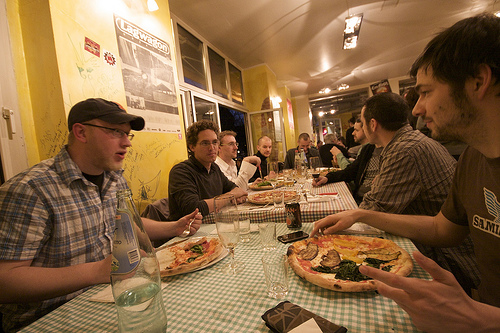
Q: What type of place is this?
A: It is a restaurant.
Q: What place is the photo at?
A: It is at the restaurant.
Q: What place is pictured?
A: It is a restaurant.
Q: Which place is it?
A: It is a restaurant.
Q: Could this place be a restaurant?
A: Yes, it is a restaurant.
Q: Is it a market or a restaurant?
A: It is a restaurant.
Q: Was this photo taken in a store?
A: No, the picture was taken in a restaurant.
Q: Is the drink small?
A: Yes, the drink is small.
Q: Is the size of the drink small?
A: Yes, the drink is small.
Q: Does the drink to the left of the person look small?
A: Yes, the drink is small.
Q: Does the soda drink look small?
A: Yes, the drink is small.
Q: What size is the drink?
A: The drink is small.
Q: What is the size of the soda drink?
A: The drink is small.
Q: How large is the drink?
A: The drink is small.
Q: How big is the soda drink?
A: The drink is small.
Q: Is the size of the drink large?
A: No, the drink is small.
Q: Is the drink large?
A: No, the drink is small.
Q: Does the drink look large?
A: No, the drink is small.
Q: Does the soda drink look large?
A: No, the drink is small.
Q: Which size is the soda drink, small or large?
A: The drink is small.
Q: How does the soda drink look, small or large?
A: The drink is small.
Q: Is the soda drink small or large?
A: The drink is small.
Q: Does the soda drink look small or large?
A: The drink is small.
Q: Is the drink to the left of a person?
A: Yes, the drink is to the left of a person.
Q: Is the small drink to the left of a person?
A: Yes, the drink is to the left of a person.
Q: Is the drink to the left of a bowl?
A: No, the drink is to the left of a person.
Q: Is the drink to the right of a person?
A: No, the drink is to the left of a person.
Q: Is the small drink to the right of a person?
A: No, the drink is to the left of a person.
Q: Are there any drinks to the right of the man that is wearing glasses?
A: Yes, there is a drink to the right of the man.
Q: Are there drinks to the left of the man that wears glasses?
A: No, the drink is to the right of the man.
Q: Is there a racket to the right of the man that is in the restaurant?
A: No, there is a drink to the right of the man.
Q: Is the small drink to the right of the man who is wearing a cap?
A: Yes, the drink is to the right of the man.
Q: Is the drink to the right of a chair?
A: No, the drink is to the right of the man.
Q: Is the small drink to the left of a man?
A: No, the drink is to the right of a man.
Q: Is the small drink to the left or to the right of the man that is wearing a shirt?
A: The drink is to the right of the man.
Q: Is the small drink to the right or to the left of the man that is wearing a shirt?
A: The drink is to the right of the man.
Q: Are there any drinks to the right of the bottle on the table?
A: Yes, there is a drink to the right of the bottle.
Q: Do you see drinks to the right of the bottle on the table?
A: Yes, there is a drink to the right of the bottle.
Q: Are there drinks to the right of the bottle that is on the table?
A: Yes, there is a drink to the right of the bottle.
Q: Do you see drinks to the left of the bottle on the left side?
A: No, the drink is to the right of the bottle.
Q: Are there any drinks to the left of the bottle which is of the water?
A: No, the drink is to the right of the bottle.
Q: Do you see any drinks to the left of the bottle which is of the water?
A: No, the drink is to the right of the bottle.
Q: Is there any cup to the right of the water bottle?
A: No, there is a drink to the right of the bottle.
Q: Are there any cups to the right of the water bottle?
A: No, there is a drink to the right of the bottle.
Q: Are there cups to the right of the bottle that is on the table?
A: No, there is a drink to the right of the bottle.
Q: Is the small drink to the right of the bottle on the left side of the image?
A: Yes, the drink is to the right of the bottle.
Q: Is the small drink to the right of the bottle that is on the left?
A: Yes, the drink is to the right of the bottle.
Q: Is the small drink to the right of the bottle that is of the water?
A: Yes, the drink is to the right of the bottle.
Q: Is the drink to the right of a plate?
A: No, the drink is to the right of the bottle.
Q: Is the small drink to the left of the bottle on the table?
A: No, the drink is to the right of the bottle.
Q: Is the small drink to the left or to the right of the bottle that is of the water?
A: The drink is to the right of the bottle.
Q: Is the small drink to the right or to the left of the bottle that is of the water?
A: The drink is to the right of the bottle.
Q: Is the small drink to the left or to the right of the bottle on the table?
A: The drink is to the right of the bottle.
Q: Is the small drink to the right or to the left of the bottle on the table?
A: The drink is to the right of the bottle.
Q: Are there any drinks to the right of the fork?
A: Yes, there is a drink to the right of the fork.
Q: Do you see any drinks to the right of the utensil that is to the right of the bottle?
A: Yes, there is a drink to the right of the fork.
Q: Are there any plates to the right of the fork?
A: No, there is a drink to the right of the fork.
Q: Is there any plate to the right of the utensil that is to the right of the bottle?
A: No, there is a drink to the right of the fork.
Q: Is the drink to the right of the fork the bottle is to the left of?
A: Yes, the drink is to the right of the fork.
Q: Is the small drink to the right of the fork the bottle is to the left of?
A: Yes, the drink is to the right of the fork.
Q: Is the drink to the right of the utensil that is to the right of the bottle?
A: Yes, the drink is to the right of the fork.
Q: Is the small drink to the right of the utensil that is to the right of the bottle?
A: Yes, the drink is to the right of the fork.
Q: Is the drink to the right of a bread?
A: No, the drink is to the right of the fork.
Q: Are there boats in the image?
A: No, there are no boats.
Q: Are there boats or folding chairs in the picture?
A: No, there are no boats or folding chairs.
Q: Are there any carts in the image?
A: No, there are no carts.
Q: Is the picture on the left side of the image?
A: Yes, the picture is on the left of the image.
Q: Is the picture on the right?
A: No, the picture is on the left of the image.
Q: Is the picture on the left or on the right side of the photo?
A: The picture is on the left of the image.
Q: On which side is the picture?
A: The picture is on the left of the image.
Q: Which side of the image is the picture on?
A: The picture is on the left of the image.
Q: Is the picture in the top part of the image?
A: Yes, the picture is in the top of the image.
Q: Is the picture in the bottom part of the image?
A: No, the picture is in the top of the image.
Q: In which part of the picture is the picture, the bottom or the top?
A: The picture is in the top of the image.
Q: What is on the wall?
A: The picture is on the wall.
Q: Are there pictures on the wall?
A: Yes, there is a picture on the wall.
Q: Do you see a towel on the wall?
A: No, there is a picture on the wall.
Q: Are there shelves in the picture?
A: No, there are no shelves.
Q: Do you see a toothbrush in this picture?
A: No, there are no toothbrushes.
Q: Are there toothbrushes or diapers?
A: No, there are no toothbrushes or diapers.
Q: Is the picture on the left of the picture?
A: Yes, the picture is on the left of the image.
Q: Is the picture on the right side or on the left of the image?
A: The picture is on the left of the image.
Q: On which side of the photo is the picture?
A: The picture is on the left of the image.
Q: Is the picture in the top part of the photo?
A: Yes, the picture is in the top of the image.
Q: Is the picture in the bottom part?
A: No, the picture is in the top of the image.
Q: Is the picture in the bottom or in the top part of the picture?
A: The picture is in the top of the image.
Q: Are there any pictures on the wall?
A: Yes, there is a picture on the wall.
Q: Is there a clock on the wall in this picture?
A: No, there is a picture on the wall.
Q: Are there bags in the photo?
A: No, there are no bags.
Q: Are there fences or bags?
A: No, there are no bags or fences.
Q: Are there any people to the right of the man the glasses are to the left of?
A: Yes, there is a person to the right of the man.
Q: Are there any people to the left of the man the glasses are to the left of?
A: No, the person is to the right of the man.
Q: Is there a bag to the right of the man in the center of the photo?
A: No, there is a person to the right of the man.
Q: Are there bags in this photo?
A: No, there are no bags.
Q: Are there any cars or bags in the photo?
A: No, there are no bags or cars.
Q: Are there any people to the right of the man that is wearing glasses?
A: Yes, there is a person to the right of the man.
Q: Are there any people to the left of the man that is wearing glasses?
A: No, the person is to the right of the man.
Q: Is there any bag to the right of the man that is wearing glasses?
A: No, there is a person to the right of the man.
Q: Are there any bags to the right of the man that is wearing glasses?
A: No, there is a person to the right of the man.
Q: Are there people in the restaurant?
A: Yes, there is a person in the restaurant.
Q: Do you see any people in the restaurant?
A: Yes, there is a person in the restaurant.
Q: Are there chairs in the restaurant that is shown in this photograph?
A: No, there is a person in the restaurant.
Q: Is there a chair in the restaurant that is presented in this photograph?
A: No, there is a person in the restaurant.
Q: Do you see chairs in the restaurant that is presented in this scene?
A: No, there is a person in the restaurant.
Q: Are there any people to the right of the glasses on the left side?
A: Yes, there is a person to the right of the glasses.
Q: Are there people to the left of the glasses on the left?
A: No, the person is to the right of the glasses.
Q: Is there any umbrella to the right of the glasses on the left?
A: No, there is a person to the right of the glasses.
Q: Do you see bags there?
A: No, there are no bags.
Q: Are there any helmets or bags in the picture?
A: No, there are no bags or helmets.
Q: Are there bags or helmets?
A: No, there are no bags or helmets.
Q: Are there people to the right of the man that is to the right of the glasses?
A: Yes, there is a person to the right of the man.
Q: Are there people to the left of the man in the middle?
A: No, the person is to the right of the man.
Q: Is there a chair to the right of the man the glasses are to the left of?
A: No, there is a person to the right of the man.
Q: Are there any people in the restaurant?
A: Yes, there is a person in the restaurant.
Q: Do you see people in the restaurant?
A: Yes, there is a person in the restaurant.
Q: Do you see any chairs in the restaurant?
A: No, there is a person in the restaurant.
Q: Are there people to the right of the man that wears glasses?
A: Yes, there is a person to the right of the man.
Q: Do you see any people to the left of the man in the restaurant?
A: No, the person is to the right of the man.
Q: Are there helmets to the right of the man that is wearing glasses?
A: No, there is a person to the right of the man.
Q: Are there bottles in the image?
A: Yes, there is a bottle.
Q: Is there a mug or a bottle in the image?
A: Yes, there is a bottle.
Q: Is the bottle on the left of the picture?
A: Yes, the bottle is on the left of the image.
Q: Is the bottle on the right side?
A: No, the bottle is on the left of the image.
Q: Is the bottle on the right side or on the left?
A: The bottle is on the left of the image.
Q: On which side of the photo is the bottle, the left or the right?
A: The bottle is on the left of the image.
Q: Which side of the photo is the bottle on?
A: The bottle is on the left of the image.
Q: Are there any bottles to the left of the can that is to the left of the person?
A: Yes, there is a bottle to the left of the can.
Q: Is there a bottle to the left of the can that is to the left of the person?
A: Yes, there is a bottle to the left of the can.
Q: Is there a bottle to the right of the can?
A: No, the bottle is to the left of the can.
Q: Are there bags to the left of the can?
A: No, there is a bottle to the left of the can.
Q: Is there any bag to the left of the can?
A: No, there is a bottle to the left of the can.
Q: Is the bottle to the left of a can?
A: Yes, the bottle is to the left of a can.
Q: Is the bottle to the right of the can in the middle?
A: No, the bottle is to the left of the can.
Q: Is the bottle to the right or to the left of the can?
A: The bottle is to the left of the can.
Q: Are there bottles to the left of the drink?
A: Yes, there is a bottle to the left of the drink.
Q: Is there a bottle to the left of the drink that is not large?
A: Yes, there is a bottle to the left of the drink.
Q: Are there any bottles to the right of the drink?
A: No, the bottle is to the left of the drink.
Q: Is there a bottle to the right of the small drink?
A: No, the bottle is to the left of the drink.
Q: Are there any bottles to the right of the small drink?
A: No, the bottle is to the left of the drink.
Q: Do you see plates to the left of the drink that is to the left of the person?
A: No, there is a bottle to the left of the drink.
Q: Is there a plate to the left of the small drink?
A: No, there is a bottle to the left of the drink.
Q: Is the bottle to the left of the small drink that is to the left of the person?
A: Yes, the bottle is to the left of the drink.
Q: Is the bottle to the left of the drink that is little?
A: Yes, the bottle is to the left of the drink.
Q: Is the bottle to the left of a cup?
A: No, the bottle is to the left of the drink.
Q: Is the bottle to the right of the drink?
A: No, the bottle is to the left of the drink.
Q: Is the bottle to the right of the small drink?
A: No, the bottle is to the left of the drink.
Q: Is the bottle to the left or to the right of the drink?
A: The bottle is to the left of the drink.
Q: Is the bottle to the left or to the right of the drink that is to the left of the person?
A: The bottle is to the left of the drink.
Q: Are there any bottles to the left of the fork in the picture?
A: Yes, there is a bottle to the left of the fork.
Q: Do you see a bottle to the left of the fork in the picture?
A: Yes, there is a bottle to the left of the fork.